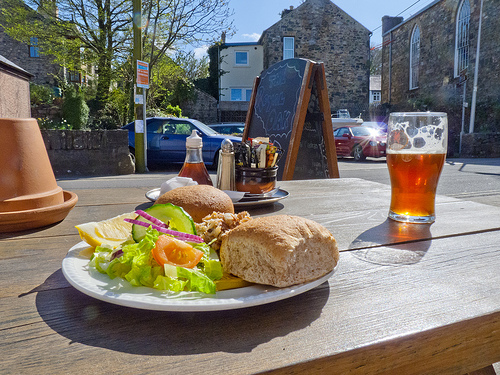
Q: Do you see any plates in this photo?
A: Yes, there is a plate.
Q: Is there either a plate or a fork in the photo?
A: Yes, there is a plate.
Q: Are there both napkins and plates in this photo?
A: No, there is a plate but no napkins.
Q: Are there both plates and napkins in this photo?
A: No, there is a plate but no napkins.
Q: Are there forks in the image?
A: No, there are no forks.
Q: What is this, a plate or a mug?
A: This is a plate.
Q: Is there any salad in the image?
A: Yes, there is salad.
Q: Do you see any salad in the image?
A: Yes, there is salad.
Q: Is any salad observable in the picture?
A: Yes, there is salad.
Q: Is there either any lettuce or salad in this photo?
A: Yes, there is salad.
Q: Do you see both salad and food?
A: Yes, there are both salad and food.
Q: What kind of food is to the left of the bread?
A: The food is salad.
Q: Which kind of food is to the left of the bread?
A: The food is salad.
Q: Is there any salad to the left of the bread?
A: Yes, there is salad to the left of the bread.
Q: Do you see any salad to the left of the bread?
A: Yes, there is salad to the left of the bread.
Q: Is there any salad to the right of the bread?
A: No, the salad is to the left of the bread.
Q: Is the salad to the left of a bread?
A: Yes, the salad is to the left of a bread.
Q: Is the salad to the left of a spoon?
A: No, the salad is to the left of a bread.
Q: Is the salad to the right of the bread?
A: No, the salad is to the left of the bread.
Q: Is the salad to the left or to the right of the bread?
A: The salad is to the left of the bread.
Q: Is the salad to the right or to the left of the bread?
A: The salad is to the left of the bread.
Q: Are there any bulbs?
A: No, there are no bulbs.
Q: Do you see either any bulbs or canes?
A: No, there are no bulbs or canes.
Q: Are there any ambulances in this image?
A: No, there are no ambulances.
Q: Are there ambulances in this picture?
A: No, there are no ambulances.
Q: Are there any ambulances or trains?
A: No, there are no ambulances or trains.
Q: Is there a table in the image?
A: Yes, there is a table.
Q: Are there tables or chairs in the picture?
A: Yes, there is a table.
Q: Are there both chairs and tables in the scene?
A: No, there is a table but no chairs.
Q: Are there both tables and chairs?
A: No, there is a table but no chairs.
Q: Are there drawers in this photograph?
A: No, there are no drawers.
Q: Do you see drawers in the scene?
A: No, there are no drawers.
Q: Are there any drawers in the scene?
A: No, there are no drawers.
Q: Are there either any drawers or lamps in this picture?
A: No, there are no drawers or lamps.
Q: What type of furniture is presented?
A: The furniture is a table.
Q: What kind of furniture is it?
A: The piece of furniture is a table.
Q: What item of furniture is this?
A: This is a table.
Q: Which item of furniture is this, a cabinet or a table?
A: This is a table.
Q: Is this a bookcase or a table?
A: This is a table.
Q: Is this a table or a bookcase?
A: This is a table.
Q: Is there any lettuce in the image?
A: Yes, there is lettuce.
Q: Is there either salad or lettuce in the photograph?
A: Yes, there is lettuce.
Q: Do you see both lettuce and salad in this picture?
A: Yes, there are both lettuce and salad.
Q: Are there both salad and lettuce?
A: Yes, there are both lettuce and salad.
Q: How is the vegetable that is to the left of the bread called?
A: The vegetable is lettuce.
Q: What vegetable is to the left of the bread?
A: The vegetable is lettuce.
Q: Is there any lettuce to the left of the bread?
A: Yes, there is lettuce to the left of the bread.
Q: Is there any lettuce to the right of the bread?
A: No, the lettuce is to the left of the bread.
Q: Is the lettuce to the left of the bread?
A: Yes, the lettuce is to the left of the bread.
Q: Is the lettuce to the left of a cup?
A: No, the lettuce is to the left of the bread.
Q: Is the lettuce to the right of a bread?
A: No, the lettuce is to the left of a bread.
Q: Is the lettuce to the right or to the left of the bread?
A: The lettuce is to the left of the bread.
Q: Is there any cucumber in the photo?
A: Yes, there is a cucumber.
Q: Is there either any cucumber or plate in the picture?
A: Yes, there is a cucumber.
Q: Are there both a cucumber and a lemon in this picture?
A: Yes, there are both a cucumber and a lemon.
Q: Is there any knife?
A: No, there are no knives.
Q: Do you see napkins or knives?
A: No, there are no knives or napkins.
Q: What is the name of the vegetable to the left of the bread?
A: The vegetable is a cucumber.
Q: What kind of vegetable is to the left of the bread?
A: The vegetable is a cucumber.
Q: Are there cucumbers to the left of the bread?
A: Yes, there is a cucumber to the left of the bread.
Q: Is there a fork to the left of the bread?
A: No, there is a cucumber to the left of the bread.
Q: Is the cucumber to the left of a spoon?
A: No, the cucumber is to the left of a bread.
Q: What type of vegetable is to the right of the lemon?
A: The vegetable is a cucumber.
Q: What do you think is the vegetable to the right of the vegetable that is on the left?
A: The vegetable is a cucumber.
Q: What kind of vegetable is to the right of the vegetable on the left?
A: The vegetable is a cucumber.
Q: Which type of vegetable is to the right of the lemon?
A: The vegetable is a cucumber.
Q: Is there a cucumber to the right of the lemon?
A: Yes, there is a cucumber to the right of the lemon.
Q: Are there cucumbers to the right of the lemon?
A: Yes, there is a cucumber to the right of the lemon.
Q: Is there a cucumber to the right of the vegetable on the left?
A: Yes, there is a cucumber to the right of the lemon.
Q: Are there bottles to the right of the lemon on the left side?
A: No, there is a cucumber to the right of the lemon.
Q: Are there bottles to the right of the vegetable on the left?
A: No, there is a cucumber to the right of the lemon.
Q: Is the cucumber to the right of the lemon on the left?
A: Yes, the cucumber is to the right of the lemon.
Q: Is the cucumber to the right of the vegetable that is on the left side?
A: Yes, the cucumber is to the right of the lemon.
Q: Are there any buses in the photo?
A: No, there are no buses.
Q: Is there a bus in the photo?
A: No, there are no buses.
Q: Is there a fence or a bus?
A: No, there are no buses or fences.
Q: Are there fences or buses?
A: No, there are no buses or fences.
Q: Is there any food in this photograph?
A: Yes, there is food.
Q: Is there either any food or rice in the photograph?
A: Yes, there is food.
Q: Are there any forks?
A: No, there are no forks.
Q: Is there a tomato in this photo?
A: Yes, there is a tomato.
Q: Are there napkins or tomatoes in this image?
A: Yes, there is a tomato.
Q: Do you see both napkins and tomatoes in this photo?
A: No, there is a tomato but no napkins.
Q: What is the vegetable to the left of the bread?
A: The vegetable is a tomato.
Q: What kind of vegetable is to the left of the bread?
A: The vegetable is a tomato.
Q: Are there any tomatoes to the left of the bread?
A: Yes, there is a tomato to the left of the bread.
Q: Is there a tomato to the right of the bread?
A: No, the tomato is to the left of the bread.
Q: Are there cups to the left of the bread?
A: No, there is a tomato to the left of the bread.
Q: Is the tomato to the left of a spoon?
A: No, the tomato is to the left of the bread.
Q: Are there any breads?
A: Yes, there is a bread.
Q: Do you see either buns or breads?
A: Yes, there is a bread.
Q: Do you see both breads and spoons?
A: No, there is a bread but no spoons.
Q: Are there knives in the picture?
A: No, there are no knives.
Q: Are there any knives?
A: No, there are no knives.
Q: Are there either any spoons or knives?
A: No, there are no knives or spoons.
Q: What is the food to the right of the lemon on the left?
A: The food is a bread.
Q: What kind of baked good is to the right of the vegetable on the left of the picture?
A: The food is a bread.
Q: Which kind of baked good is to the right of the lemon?
A: The food is a bread.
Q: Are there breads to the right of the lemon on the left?
A: Yes, there is a bread to the right of the lemon.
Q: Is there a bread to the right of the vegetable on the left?
A: Yes, there is a bread to the right of the lemon.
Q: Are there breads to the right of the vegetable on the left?
A: Yes, there is a bread to the right of the lemon.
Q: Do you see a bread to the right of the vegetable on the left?
A: Yes, there is a bread to the right of the lemon.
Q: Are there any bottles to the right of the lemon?
A: No, there is a bread to the right of the lemon.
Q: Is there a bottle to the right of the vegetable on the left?
A: No, there is a bread to the right of the lemon.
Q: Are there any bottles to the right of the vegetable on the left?
A: No, there is a bread to the right of the lemon.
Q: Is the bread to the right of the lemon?
A: Yes, the bread is to the right of the lemon.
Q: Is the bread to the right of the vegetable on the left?
A: Yes, the bread is to the right of the lemon.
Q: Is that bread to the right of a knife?
A: No, the bread is to the right of the lemon.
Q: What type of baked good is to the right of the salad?
A: The food is a bread.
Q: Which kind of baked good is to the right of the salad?
A: The food is a bread.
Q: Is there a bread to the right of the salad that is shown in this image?
A: Yes, there is a bread to the right of the salad.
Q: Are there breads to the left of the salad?
A: No, the bread is to the right of the salad.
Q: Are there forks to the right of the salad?
A: No, there is a bread to the right of the salad.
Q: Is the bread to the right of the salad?
A: Yes, the bread is to the right of the salad.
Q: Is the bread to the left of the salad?
A: No, the bread is to the right of the salad.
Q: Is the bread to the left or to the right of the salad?
A: The bread is to the right of the salad.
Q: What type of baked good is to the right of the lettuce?
A: The food is a bread.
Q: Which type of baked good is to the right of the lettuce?
A: The food is a bread.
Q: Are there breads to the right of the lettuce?
A: Yes, there is a bread to the right of the lettuce.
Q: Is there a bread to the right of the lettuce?
A: Yes, there is a bread to the right of the lettuce.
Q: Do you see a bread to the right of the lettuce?
A: Yes, there is a bread to the right of the lettuce.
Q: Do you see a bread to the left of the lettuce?
A: No, the bread is to the right of the lettuce.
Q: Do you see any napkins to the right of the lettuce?
A: No, there is a bread to the right of the lettuce.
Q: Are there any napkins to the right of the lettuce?
A: No, there is a bread to the right of the lettuce.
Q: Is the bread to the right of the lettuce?
A: Yes, the bread is to the right of the lettuce.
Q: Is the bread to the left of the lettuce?
A: No, the bread is to the right of the lettuce.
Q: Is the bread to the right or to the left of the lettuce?
A: The bread is to the right of the lettuce.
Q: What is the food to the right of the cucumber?
A: The food is a bread.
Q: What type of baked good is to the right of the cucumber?
A: The food is a bread.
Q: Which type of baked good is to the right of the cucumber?
A: The food is a bread.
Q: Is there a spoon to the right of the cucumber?
A: No, there is a bread to the right of the cucumber.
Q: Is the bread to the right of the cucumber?
A: Yes, the bread is to the right of the cucumber.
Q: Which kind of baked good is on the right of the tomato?
A: The food is a bread.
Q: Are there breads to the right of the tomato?
A: Yes, there is a bread to the right of the tomato.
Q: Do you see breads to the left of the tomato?
A: No, the bread is to the right of the tomato.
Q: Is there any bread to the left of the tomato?
A: No, the bread is to the right of the tomato.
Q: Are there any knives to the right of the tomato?
A: No, there is a bread to the right of the tomato.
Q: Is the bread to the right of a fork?
A: No, the bread is to the right of the tomato.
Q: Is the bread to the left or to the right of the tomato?
A: The bread is to the right of the tomato.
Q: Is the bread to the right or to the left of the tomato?
A: The bread is to the right of the tomato.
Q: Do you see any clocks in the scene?
A: No, there are no clocks.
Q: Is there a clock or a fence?
A: No, there are no clocks or fences.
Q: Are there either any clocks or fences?
A: No, there are no clocks or fences.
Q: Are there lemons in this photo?
A: Yes, there is a lemon.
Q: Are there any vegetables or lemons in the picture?
A: Yes, there is a lemon.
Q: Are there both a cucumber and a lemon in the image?
A: Yes, there are both a lemon and a cucumber.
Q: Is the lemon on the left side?
A: Yes, the lemon is on the left of the image.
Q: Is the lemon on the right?
A: No, the lemon is on the left of the image.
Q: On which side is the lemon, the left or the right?
A: The lemon is on the left of the image.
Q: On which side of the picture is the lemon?
A: The lemon is on the left of the image.